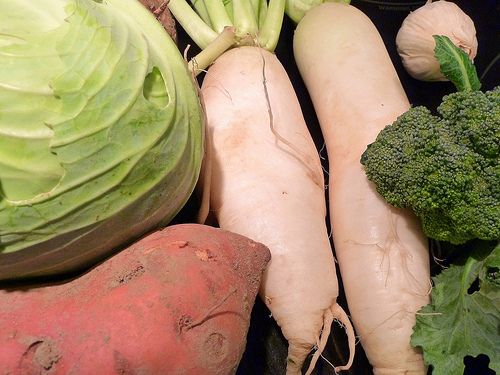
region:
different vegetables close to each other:
[20, 7, 460, 348]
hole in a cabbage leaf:
[126, 45, 178, 135]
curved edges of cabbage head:
[30, 10, 100, 210]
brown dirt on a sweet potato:
[10, 227, 265, 363]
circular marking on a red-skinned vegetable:
[186, 321, 231, 361]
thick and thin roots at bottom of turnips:
[280, 280, 360, 372]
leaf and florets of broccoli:
[430, 107, 495, 332]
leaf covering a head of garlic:
[390, 0, 495, 91]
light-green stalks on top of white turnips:
[150, 0, 350, 90]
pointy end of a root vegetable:
[186, 215, 282, 305]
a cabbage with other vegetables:
[0, 55, 182, 231]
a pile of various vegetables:
[24, 19, 499, 311]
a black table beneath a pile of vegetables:
[304, 14, 499, 229]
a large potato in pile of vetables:
[8, 274, 313, 374]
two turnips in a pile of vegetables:
[223, 39, 415, 351]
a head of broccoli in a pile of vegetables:
[395, 114, 498, 206]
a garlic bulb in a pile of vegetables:
[389, 4, 479, 84]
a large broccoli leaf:
[433, 254, 498, 362]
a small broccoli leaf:
[430, 34, 475, 106]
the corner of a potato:
[117, 1, 188, 46]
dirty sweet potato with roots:
[0, 222, 265, 370]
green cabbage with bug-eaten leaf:
[2, 1, 225, 261]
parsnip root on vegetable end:
[308, 293, 364, 373]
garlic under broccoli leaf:
[387, 3, 486, 88]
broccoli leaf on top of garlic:
[430, 32, 476, 89]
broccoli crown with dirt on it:
[361, 82, 496, 243]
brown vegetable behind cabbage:
[135, 0, 182, 45]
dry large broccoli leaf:
[406, 245, 497, 372]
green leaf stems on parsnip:
[169, 0, 292, 52]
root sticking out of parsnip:
[255, 43, 323, 192]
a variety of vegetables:
[52, 39, 482, 333]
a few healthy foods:
[75, 16, 469, 341]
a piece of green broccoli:
[351, 62, 497, 225]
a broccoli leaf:
[399, 238, 496, 372]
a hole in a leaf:
[123, 56, 193, 136]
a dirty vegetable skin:
[91, 235, 215, 328]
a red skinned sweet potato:
[8, 193, 276, 373]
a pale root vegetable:
[186, 21, 382, 372]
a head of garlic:
[378, 1, 494, 86]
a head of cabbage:
[0, 0, 215, 263]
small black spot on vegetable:
[245, 51, 296, 139]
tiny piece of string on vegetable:
[313, 346, 341, 373]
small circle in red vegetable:
[184, 328, 241, 374]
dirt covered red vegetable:
[93, 258, 196, 294]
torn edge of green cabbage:
[13, 106, 110, 222]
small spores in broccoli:
[393, 127, 456, 172]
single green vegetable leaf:
[422, 26, 487, 93]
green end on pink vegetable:
[198, 23, 289, 68]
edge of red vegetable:
[235, 226, 284, 273]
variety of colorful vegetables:
[49, 23, 476, 293]